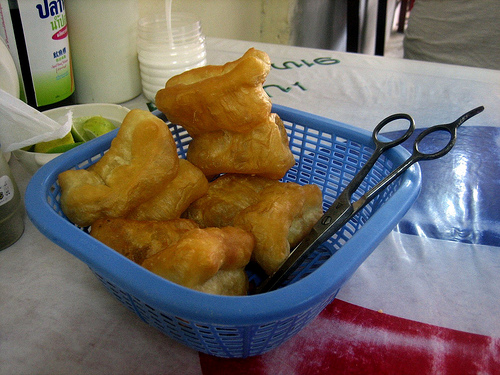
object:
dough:
[87, 217, 257, 294]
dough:
[186, 174, 324, 274]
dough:
[55, 101, 207, 238]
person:
[343, 129, 462, 161]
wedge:
[74, 117, 119, 146]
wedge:
[35, 128, 74, 155]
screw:
[322, 214, 335, 226]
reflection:
[421, 154, 485, 236]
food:
[147, 57, 329, 274]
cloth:
[345, 299, 499, 358]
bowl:
[17, 102, 140, 178]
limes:
[23, 117, 112, 152]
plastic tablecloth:
[376, 130, 498, 248]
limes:
[80, 115, 117, 139]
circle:
[267, 124, 497, 364]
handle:
[344, 116, 484, 200]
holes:
[306, 135, 317, 141]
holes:
[342, 172, 352, 180]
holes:
[292, 125, 303, 130]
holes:
[322, 186, 335, 197]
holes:
[286, 174, 295, 179]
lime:
[34, 123, 77, 155]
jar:
[133, 19, 206, 106]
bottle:
[136, 12, 208, 104]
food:
[59, 96, 252, 295]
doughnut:
[150, 49, 291, 182]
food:
[58, 44, 323, 279]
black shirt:
[258, 95, 488, 290]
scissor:
[255, 100, 484, 290]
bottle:
[66, 0, 140, 105]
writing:
[34, 0, 71, 31]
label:
[17, 0, 77, 108]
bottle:
[1, 0, 78, 110]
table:
[0, 33, 500, 373]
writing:
[260, 57, 341, 99]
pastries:
[178, 152, 225, 210]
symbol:
[0, 171, 16, 208]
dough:
[155, 48, 296, 179]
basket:
[23, 104, 422, 358]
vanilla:
[11, 1, 74, 107]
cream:
[135, 44, 205, 104]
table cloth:
[2, 35, 496, 373]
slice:
[68, 115, 119, 145]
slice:
[25, 128, 73, 150]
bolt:
[318, 215, 333, 226]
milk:
[139, 39, 205, 104]